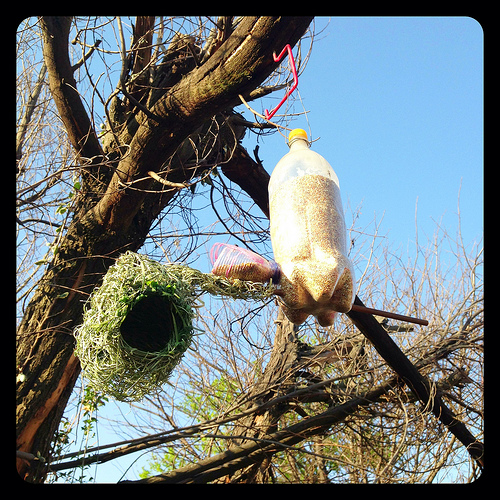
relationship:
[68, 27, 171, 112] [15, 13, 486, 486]
branches in tree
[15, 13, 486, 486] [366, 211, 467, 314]
tree has branches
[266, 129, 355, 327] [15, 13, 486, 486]
bottle hanging in tree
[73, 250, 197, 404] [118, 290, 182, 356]
nest has a hole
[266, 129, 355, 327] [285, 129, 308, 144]
bottle has a top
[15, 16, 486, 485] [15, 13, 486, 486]
sky above tree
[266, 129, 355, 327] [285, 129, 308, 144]
bottle has top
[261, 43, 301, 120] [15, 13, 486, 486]
thing on tree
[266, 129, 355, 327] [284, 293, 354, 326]
bottle has a bottom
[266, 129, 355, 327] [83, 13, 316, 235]
bottle hangs from branch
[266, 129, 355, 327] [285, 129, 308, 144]
bottle has a cap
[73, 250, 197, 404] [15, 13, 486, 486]
nest in tree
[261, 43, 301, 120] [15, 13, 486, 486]
hook hangs in tree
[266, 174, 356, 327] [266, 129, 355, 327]
seed inside of bottle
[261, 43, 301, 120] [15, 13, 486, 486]
hook on tree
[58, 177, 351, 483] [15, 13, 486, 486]
leaves are on tree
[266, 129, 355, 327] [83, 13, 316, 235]
plastic hanging from branch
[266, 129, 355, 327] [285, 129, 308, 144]
bottle has cap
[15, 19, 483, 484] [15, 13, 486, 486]
vines are hanging from tree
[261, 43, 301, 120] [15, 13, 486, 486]
hook hanging from tree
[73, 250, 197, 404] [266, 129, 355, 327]
nest attached to bottle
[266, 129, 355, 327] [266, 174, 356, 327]
bottle has seed